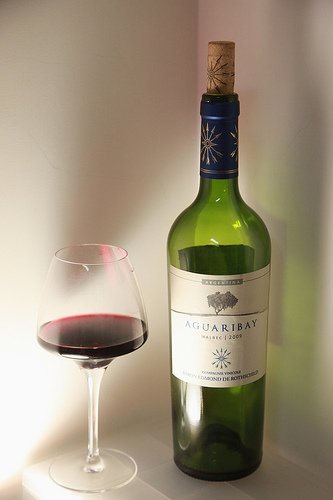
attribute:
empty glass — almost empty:
[35, 242, 149, 494]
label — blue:
[196, 98, 244, 185]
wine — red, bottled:
[150, 31, 275, 485]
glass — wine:
[151, 17, 306, 391]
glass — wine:
[37, 238, 151, 493]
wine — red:
[34, 312, 149, 367]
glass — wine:
[19, 224, 198, 498]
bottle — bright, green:
[157, 33, 279, 491]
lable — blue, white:
[166, 261, 270, 385]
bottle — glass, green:
[165, 39, 272, 483]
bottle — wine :
[141, 98, 282, 414]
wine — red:
[31, 308, 158, 365]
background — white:
[0, 1, 331, 497]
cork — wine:
[182, 37, 265, 100]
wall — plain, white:
[198, 5, 327, 259]